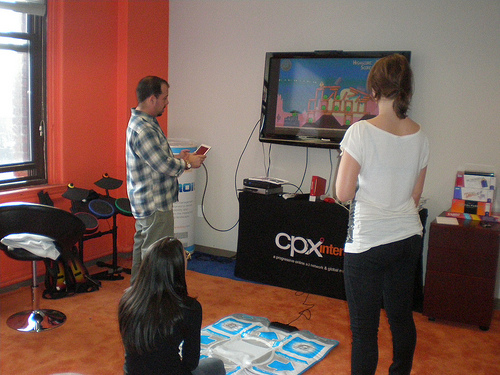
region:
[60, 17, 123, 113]
a wall painted dark orange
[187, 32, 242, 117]
a wall painted white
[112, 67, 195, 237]
a man in a plaid shirt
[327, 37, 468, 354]
a woman in a white shirt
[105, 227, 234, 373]
a woman with long dark hair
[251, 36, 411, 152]
a black flat screen TV on wall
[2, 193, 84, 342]
a black leather swivel chair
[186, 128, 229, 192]
video game controller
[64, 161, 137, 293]
a colorful electronic drum set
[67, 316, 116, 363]
orange carpet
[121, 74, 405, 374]
people playing video games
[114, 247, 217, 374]
a woman sitting on the floor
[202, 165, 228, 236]
a black connecting the tv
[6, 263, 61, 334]
a chrome base on chair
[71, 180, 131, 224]
a set of black drums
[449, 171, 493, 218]
a colorful box on a cart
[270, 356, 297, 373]
a blue arrow on a mat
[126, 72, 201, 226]
a man wearing a plaid shirt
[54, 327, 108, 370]
orange carpet on the floor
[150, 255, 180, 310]
dark brown shiny hair on head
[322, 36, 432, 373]
The woman in a white shirt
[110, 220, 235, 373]
The woman sitting on the ground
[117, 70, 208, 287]
The man in the flannel shirt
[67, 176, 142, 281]
The electronic drum set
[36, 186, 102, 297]
The two guitar hero guitars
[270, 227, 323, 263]
The large white writing on the black table cloth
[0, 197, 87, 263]
The black bowl chair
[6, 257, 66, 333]
The silver base to the black bowl chair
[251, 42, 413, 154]
The tv on the wall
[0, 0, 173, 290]
The bright orange wall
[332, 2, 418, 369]
a person watching tv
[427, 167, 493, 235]
books on a counter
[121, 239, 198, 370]
a girl sitting on the floor wearing black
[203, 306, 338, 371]
blue and gold game is on the floor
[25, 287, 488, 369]
orange carpet on floor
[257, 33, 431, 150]
TV on wall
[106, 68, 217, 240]
a man holding a controller for tv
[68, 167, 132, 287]
black electronic drum set in corner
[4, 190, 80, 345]
black chair with a white shirt sitting in it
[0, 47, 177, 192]
orange walls next to a window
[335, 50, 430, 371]
Woman looking at the TV screen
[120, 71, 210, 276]
Man looking at the TV screen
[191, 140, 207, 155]
Cellphone in the man's hands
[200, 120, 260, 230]
Cable connects the TV and the cellphone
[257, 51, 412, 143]
TV on the wall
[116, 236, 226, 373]
Woman sitting on the floor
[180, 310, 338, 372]
Cloth on the floor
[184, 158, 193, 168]
Watch on the man's right wrist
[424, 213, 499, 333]
Wood stand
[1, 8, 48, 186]
Window on the wall